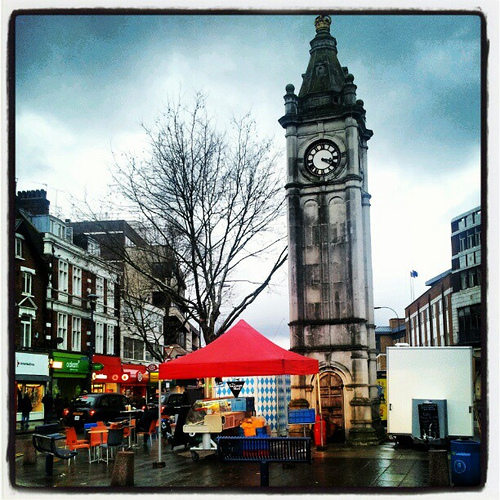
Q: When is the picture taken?
A: Daytime.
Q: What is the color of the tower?
A: Grey.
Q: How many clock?
A: 1.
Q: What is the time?
A: 3:20.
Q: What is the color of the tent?
A: Red.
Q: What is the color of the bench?
A: Black.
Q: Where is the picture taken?
A: Town center.